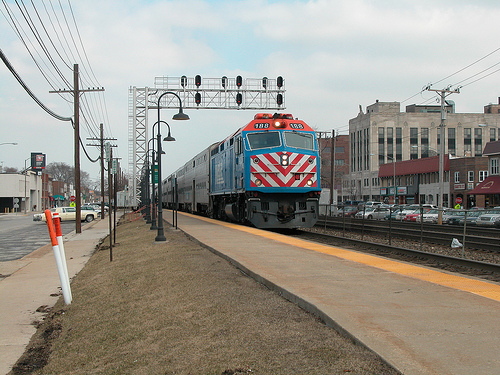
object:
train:
[152, 111, 323, 231]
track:
[304, 230, 499, 280]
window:
[245, 130, 282, 150]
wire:
[71, 27, 88, 54]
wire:
[58, 32, 71, 49]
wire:
[43, 25, 62, 51]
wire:
[34, 47, 55, 64]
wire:
[28, 60, 49, 80]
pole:
[61, 60, 93, 243]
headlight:
[272, 120, 282, 130]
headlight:
[281, 154, 288, 170]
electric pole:
[49, 63, 104, 233]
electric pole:
[429, 82, 455, 223]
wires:
[0, 0, 116, 171]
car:
[33, 206, 98, 223]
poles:
[40, 207, 73, 305]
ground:
[57, 307, 222, 368]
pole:
[96, 120, 106, 220]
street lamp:
[155, 89, 188, 244]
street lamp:
[149, 120, 173, 231]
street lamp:
[146, 133, 164, 228]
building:
[347, 99, 499, 202]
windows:
[409, 127, 419, 160]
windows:
[420, 126, 429, 158]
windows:
[377, 126, 385, 166]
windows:
[472, 123, 483, 156]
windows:
[447, 127, 456, 158]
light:
[277, 94, 282, 106]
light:
[276, 75, 284, 87]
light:
[236, 75, 243, 86]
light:
[194, 93, 201, 104]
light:
[236, 93, 243, 104]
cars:
[333, 206, 361, 219]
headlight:
[306, 178, 314, 187]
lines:
[41, 114, 126, 162]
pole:
[322, 125, 339, 212]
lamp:
[151, 90, 190, 243]